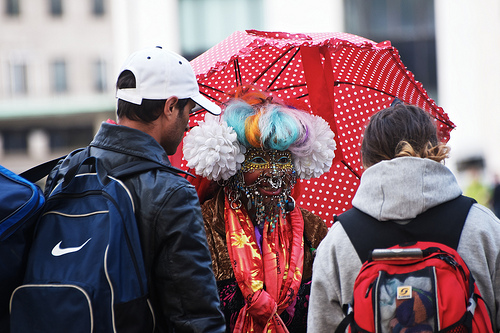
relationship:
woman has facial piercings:
[183, 93, 337, 332] [216, 145, 299, 225]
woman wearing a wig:
[183, 93, 337, 332] [223, 90, 312, 151]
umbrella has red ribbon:
[165, 28, 456, 231] [299, 41, 344, 163]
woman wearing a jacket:
[183, 93, 337, 332] [201, 198, 330, 332]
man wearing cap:
[10, 47, 227, 331] [115, 44, 221, 116]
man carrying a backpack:
[10, 47, 227, 331] [8, 157, 161, 332]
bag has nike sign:
[8, 157, 161, 332] [51, 238, 93, 256]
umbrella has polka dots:
[165, 28, 456, 231] [166, 28, 454, 237]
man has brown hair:
[10, 47, 227, 331] [116, 69, 190, 118]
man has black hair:
[10, 47, 227, 331] [116, 69, 190, 118]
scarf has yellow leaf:
[225, 187, 305, 332] [229, 228, 263, 290]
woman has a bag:
[308, 103, 500, 332] [335, 239, 492, 332]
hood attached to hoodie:
[352, 155, 464, 221] [305, 156, 499, 332]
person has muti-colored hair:
[183, 93, 337, 332] [223, 90, 312, 151]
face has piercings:
[221, 144, 296, 226] [216, 145, 299, 225]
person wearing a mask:
[183, 93, 337, 332] [239, 145, 295, 205]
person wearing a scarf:
[183, 93, 337, 332] [225, 187, 305, 332]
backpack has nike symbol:
[8, 157, 161, 332] [51, 238, 93, 256]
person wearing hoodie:
[308, 103, 500, 332] [305, 156, 499, 332]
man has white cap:
[10, 47, 227, 331] [115, 44, 221, 116]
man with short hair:
[10, 47, 227, 331] [116, 69, 190, 118]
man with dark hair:
[10, 47, 227, 331] [116, 69, 190, 118]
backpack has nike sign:
[8, 157, 161, 332] [51, 238, 93, 256]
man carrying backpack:
[10, 47, 227, 331] [8, 157, 161, 332]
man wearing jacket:
[10, 47, 227, 331] [46, 123, 225, 332]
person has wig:
[183, 93, 337, 332] [223, 90, 312, 151]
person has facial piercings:
[183, 93, 337, 332] [216, 145, 299, 225]